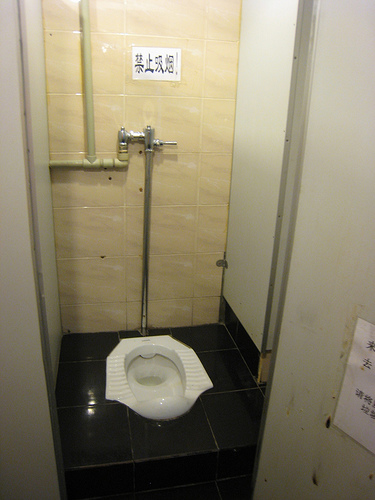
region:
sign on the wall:
[126, 41, 191, 90]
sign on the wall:
[320, 300, 374, 452]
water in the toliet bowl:
[139, 368, 167, 396]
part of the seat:
[110, 354, 125, 397]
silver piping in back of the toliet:
[117, 191, 170, 332]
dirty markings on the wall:
[280, 401, 333, 487]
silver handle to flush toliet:
[157, 138, 191, 160]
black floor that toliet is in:
[78, 423, 119, 453]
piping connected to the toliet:
[48, 141, 143, 183]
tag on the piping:
[253, 348, 269, 388]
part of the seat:
[154, 335, 178, 346]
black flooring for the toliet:
[119, 433, 155, 456]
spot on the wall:
[103, 173, 114, 184]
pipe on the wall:
[128, 172, 162, 334]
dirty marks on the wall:
[291, 409, 331, 494]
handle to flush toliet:
[155, 138, 180, 148]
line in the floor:
[108, 422, 146, 458]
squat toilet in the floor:
[104, 333, 213, 421]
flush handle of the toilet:
[142, 128, 178, 152]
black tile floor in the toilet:
[58, 322, 262, 467]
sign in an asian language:
[132, 47, 180, 79]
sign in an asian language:
[332, 317, 374, 453]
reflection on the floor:
[83, 389, 97, 418]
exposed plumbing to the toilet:
[46, 4, 158, 326]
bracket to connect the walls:
[214, 258, 229, 270]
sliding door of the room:
[255, 80, 310, 385]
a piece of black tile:
[54, 401, 132, 466]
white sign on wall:
[135, 44, 184, 84]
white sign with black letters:
[128, 44, 184, 82]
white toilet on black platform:
[98, 332, 227, 420]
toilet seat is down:
[100, 332, 214, 415]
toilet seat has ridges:
[96, 338, 219, 416]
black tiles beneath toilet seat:
[54, 389, 141, 459]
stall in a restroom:
[19, 37, 357, 486]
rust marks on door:
[278, 384, 344, 492]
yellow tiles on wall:
[177, 105, 234, 183]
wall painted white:
[235, 118, 259, 235]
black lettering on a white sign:
[133, 48, 182, 80]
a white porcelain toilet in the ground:
[98, 329, 206, 423]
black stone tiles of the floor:
[89, 413, 162, 454]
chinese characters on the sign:
[134, 51, 179, 76]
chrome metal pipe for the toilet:
[118, 120, 167, 331]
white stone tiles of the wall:
[165, 156, 218, 276]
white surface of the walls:
[237, 110, 273, 188]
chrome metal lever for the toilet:
[146, 132, 181, 151]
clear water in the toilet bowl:
[135, 365, 164, 387]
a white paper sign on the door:
[333, 318, 373, 446]